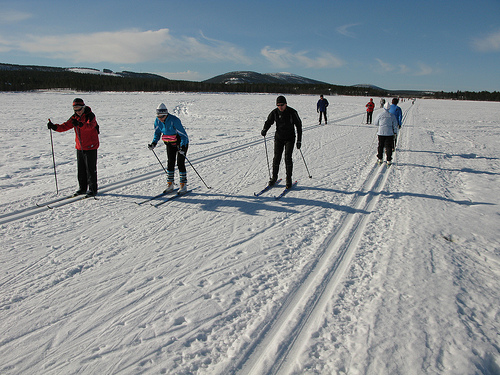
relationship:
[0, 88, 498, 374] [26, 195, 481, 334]
snow covers ground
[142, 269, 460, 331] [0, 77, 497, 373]
snow on ground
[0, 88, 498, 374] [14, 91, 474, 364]
snow on ground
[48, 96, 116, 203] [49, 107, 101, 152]
person wearing coat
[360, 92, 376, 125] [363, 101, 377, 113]
person wearing red jacket